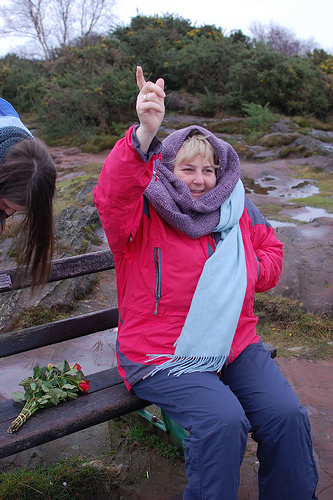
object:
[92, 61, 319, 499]
woman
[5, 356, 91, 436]
bouquet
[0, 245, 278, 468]
bench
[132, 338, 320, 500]
blue pants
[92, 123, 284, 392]
jacket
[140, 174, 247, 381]
blue scarf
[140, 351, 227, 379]
fringe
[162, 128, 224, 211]
head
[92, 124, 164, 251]
arm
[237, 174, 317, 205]
water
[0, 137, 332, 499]
ground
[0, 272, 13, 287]
plaque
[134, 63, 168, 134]
hand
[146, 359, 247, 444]
thigh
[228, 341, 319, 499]
leg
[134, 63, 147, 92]
finger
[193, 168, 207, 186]
nose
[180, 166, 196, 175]
eye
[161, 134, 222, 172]
hair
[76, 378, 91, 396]
flowers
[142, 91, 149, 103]
ring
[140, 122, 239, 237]
purple scarf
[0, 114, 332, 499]
park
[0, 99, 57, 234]
girl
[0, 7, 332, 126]
trees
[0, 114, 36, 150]
blue scarf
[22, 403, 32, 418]
rubber bands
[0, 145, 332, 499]
dirt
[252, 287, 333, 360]
grass